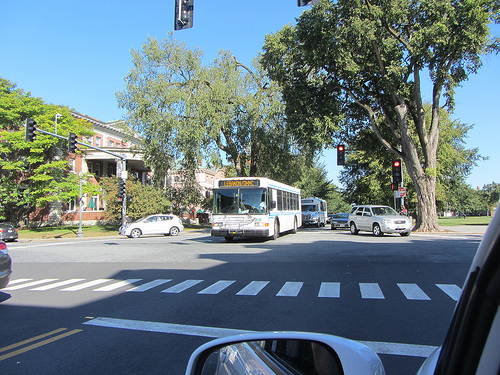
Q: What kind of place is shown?
A: It is a road.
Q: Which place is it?
A: It is a road.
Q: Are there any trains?
A: No, there are no trains.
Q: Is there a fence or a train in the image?
A: No, there are no trains or fences.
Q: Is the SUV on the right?
A: Yes, the SUV is on the right of the image.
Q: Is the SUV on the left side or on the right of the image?
A: The SUV is on the right of the image.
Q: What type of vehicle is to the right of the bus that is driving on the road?
A: The vehicle is a SUV.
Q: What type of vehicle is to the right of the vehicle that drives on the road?
A: The vehicle is a SUV.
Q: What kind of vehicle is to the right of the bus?
A: The vehicle is a SUV.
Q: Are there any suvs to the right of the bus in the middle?
A: Yes, there is a SUV to the right of the bus.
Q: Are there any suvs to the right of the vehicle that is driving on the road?
A: Yes, there is a SUV to the right of the bus.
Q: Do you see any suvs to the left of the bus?
A: No, the SUV is to the right of the bus.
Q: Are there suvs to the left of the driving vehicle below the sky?
A: No, the SUV is to the right of the bus.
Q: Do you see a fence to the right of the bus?
A: No, there is a SUV to the right of the bus.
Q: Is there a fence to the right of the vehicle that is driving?
A: No, there is a SUV to the right of the bus.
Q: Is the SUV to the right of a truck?
A: No, the SUV is to the right of the bus.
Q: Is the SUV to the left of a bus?
A: No, the SUV is to the right of a bus.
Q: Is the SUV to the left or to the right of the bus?
A: The SUV is to the right of the bus.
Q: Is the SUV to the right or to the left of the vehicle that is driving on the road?
A: The SUV is to the right of the bus.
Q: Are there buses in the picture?
A: Yes, there is a bus.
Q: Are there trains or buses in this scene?
A: Yes, there is a bus.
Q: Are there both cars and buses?
A: Yes, there are both a bus and a car.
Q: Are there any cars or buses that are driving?
A: Yes, the bus is driving.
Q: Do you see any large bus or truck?
A: Yes, there is a large bus.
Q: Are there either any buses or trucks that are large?
A: Yes, the bus is large.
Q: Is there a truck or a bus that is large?
A: Yes, the bus is large.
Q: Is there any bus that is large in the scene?
A: Yes, there is a large bus.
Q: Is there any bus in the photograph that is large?
A: Yes, there is a bus that is large.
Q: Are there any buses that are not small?
A: Yes, there is a large bus.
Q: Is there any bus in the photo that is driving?
A: Yes, there is a bus that is driving.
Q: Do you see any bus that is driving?
A: Yes, there is a bus that is driving.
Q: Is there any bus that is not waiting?
A: Yes, there is a bus that is driving.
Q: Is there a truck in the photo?
A: No, there are no trucks.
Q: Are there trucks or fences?
A: No, there are no trucks or fences.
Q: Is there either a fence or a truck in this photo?
A: No, there are no trucks or fences.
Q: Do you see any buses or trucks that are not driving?
A: No, there is a bus but it is driving.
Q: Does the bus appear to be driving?
A: Yes, the bus is driving.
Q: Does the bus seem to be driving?
A: Yes, the bus is driving.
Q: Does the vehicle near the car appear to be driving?
A: Yes, the bus is driving.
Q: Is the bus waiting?
A: No, the bus is driving.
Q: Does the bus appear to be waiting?
A: No, the bus is driving.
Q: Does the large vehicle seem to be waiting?
A: No, the bus is driving.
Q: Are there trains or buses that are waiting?
A: No, there is a bus but it is driving.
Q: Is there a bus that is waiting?
A: No, there is a bus but it is driving.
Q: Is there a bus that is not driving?
A: No, there is a bus but it is driving.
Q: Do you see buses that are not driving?
A: No, there is a bus but it is driving.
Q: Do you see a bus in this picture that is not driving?
A: No, there is a bus but it is driving.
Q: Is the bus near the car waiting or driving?
A: The bus is driving.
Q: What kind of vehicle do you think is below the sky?
A: The vehicle is a bus.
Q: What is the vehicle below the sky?
A: The vehicle is a bus.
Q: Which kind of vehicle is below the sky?
A: The vehicle is a bus.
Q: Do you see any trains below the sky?
A: No, there is a bus below the sky.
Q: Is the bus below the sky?
A: Yes, the bus is below the sky.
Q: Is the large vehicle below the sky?
A: Yes, the bus is below the sky.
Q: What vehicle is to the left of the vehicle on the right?
A: The vehicle is a bus.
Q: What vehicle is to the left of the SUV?
A: The vehicle is a bus.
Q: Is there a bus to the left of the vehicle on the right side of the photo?
A: Yes, there is a bus to the left of the SUV.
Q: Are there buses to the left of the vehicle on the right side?
A: Yes, there is a bus to the left of the SUV.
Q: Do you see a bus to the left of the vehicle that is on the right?
A: Yes, there is a bus to the left of the SUV.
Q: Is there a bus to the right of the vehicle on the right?
A: No, the bus is to the left of the SUV.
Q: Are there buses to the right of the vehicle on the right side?
A: No, the bus is to the left of the SUV.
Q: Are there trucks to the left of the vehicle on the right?
A: No, there is a bus to the left of the SUV.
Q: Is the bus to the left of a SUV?
A: Yes, the bus is to the left of a SUV.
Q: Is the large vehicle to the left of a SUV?
A: Yes, the bus is to the left of a SUV.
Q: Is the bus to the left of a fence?
A: No, the bus is to the left of a SUV.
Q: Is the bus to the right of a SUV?
A: No, the bus is to the left of a SUV.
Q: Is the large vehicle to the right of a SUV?
A: No, the bus is to the left of a SUV.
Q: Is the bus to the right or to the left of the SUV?
A: The bus is to the left of the SUV.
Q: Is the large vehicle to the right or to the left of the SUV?
A: The bus is to the left of the SUV.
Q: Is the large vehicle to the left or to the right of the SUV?
A: The bus is to the left of the SUV.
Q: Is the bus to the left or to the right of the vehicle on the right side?
A: The bus is to the left of the SUV.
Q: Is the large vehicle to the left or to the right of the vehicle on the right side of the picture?
A: The bus is to the left of the SUV.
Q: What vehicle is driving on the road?
A: The vehicle is a bus.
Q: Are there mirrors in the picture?
A: Yes, there is a mirror.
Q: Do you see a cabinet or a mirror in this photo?
A: Yes, there is a mirror.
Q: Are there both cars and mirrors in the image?
A: Yes, there are both a mirror and a car.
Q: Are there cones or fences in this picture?
A: No, there are no fences or cones.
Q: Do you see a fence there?
A: No, there are no fences.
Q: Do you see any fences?
A: No, there are no fences.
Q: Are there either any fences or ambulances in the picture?
A: No, there are no fences or ambulances.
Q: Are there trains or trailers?
A: No, there are no trains or trailers.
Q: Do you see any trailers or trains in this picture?
A: No, there are no trains or trailers.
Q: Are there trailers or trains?
A: No, there are no trains or trailers.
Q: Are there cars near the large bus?
A: Yes, there is a car near the bus.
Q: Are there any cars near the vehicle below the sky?
A: Yes, there is a car near the bus.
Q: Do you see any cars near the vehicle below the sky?
A: Yes, there is a car near the bus.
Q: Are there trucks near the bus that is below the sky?
A: No, there is a car near the bus.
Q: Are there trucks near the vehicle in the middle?
A: No, there is a car near the bus.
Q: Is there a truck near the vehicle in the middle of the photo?
A: No, there is a car near the bus.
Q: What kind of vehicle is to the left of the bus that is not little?
A: The vehicle is a car.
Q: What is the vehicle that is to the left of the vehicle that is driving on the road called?
A: The vehicle is a car.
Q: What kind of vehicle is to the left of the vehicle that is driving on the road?
A: The vehicle is a car.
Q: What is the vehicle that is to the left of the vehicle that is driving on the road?
A: The vehicle is a car.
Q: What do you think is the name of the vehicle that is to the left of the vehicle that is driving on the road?
A: The vehicle is a car.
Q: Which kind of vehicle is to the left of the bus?
A: The vehicle is a car.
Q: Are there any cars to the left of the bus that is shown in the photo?
A: Yes, there is a car to the left of the bus.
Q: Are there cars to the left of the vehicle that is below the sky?
A: Yes, there is a car to the left of the bus.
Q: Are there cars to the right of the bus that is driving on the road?
A: No, the car is to the left of the bus.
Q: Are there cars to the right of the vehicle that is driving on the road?
A: No, the car is to the left of the bus.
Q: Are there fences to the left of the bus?
A: No, there is a car to the left of the bus.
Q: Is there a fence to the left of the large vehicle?
A: No, there is a car to the left of the bus.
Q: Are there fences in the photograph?
A: No, there are no fences.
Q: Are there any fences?
A: No, there are no fences.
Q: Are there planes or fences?
A: No, there are no fences or planes.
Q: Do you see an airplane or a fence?
A: No, there are no fences or airplanes.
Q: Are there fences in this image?
A: No, there are no fences.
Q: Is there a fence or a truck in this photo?
A: No, there are no fences or trucks.